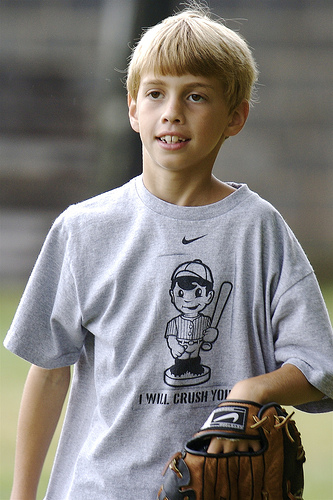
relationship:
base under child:
[162, 366, 210, 387] [166, 256, 217, 374]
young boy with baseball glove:
[68, 9, 300, 380] [181, 406, 300, 496]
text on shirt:
[138, 385, 233, 405] [4, 177, 330, 498]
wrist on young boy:
[225, 375, 271, 404] [0, 2, 333, 500]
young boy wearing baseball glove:
[0, 2, 333, 500] [156, 398, 306, 498]